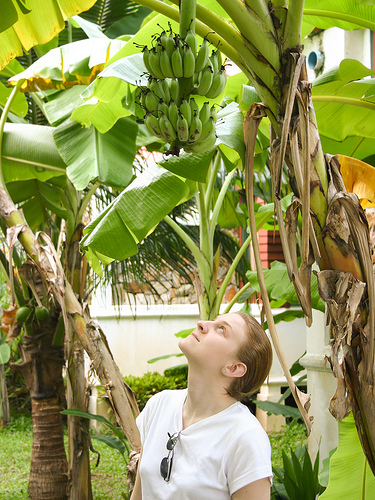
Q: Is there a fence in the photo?
A: Yes, there is a fence.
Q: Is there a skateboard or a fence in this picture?
A: Yes, there is a fence.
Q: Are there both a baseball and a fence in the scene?
A: No, there is a fence but no baseballs.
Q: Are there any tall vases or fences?
A: Yes, there is a tall fence.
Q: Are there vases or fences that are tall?
A: Yes, the fence is tall.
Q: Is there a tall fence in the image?
A: Yes, there is a tall fence.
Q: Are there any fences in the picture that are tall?
A: Yes, there is a fence that is tall.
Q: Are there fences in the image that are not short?
A: Yes, there is a tall fence.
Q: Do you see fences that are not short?
A: Yes, there is a tall fence.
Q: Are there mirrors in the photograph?
A: No, there are no mirrors.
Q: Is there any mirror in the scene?
A: No, there are no mirrors.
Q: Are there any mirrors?
A: No, there are no mirrors.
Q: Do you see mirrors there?
A: No, there are no mirrors.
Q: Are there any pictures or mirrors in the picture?
A: No, there are no mirrors or pictures.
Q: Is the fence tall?
A: Yes, the fence is tall.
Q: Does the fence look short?
A: No, the fence is tall.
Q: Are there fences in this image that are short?
A: No, there is a fence but it is tall.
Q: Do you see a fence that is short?
A: No, there is a fence but it is tall.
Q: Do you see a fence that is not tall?
A: No, there is a fence but it is tall.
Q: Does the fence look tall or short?
A: The fence is tall.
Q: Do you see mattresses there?
A: No, there are no mattresses.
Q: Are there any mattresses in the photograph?
A: No, there are no mattresses.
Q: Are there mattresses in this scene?
A: No, there are no mattresses.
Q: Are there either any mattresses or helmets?
A: No, there are no mattresses or helmets.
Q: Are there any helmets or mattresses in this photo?
A: No, there are no mattresses or helmets.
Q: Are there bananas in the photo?
A: Yes, there are bananas.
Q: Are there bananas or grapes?
A: Yes, there are bananas.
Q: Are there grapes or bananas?
A: Yes, there are bananas.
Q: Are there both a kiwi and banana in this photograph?
A: No, there are bananas but no kiwis.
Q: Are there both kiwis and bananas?
A: No, there are bananas but no kiwis.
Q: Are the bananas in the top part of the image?
A: Yes, the bananas are in the top of the image.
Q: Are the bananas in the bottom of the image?
A: No, the bananas are in the top of the image.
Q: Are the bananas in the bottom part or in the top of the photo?
A: The bananas are in the top of the image.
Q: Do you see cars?
A: No, there are no cars.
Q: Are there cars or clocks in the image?
A: No, there are no cars or clocks.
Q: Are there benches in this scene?
A: No, there are no benches.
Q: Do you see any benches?
A: No, there are no benches.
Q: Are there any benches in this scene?
A: No, there are no benches.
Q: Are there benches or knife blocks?
A: No, there are no benches or knife blocks.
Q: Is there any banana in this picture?
A: Yes, there is a banana.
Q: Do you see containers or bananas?
A: Yes, there is a banana.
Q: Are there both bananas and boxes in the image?
A: No, there is a banana but no boxes.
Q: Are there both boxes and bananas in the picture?
A: No, there is a banana but no boxes.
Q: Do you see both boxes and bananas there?
A: No, there is a banana but no boxes.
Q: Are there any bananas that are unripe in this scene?
A: Yes, there is an unripe banana.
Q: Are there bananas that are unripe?
A: Yes, there is a banana that is unripe.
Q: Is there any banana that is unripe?
A: Yes, there is a banana that is unripe.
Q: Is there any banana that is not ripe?
A: Yes, there is a unripe banana.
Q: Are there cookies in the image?
A: No, there are no cookies.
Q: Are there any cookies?
A: No, there are no cookies.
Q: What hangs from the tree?
A: The banana hangs from the tree.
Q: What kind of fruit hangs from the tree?
A: The fruit is a banana.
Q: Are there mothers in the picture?
A: No, there are no mothers.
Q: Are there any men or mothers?
A: No, there are no mothers or men.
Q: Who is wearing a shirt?
A: The girl is wearing a shirt.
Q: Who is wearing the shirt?
A: The girl is wearing a shirt.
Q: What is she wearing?
A: The girl is wearing a shirt.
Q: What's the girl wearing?
A: The girl is wearing a shirt.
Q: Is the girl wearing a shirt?
A: Yes, the girl is wearing a shirt.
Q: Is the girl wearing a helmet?
A: No, the girl is wearing a shirt.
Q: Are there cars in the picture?
A: No, there are no cars.